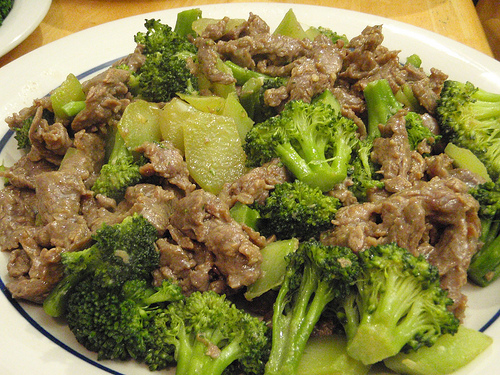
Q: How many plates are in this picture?
A: One.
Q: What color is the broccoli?
A: Green.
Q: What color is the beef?
A: Brown.